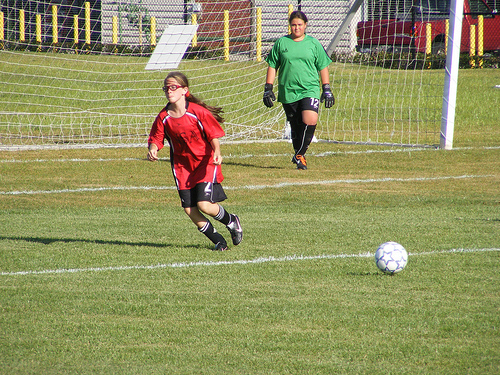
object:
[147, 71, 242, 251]
girl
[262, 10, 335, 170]
girl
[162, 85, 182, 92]
eye glass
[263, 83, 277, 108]
gloves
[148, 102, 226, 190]
shirt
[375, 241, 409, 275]
ball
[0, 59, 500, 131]
grass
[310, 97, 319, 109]
number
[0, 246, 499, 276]
line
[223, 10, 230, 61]
pole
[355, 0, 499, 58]
truck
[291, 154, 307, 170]
shoe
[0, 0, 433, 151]
goal net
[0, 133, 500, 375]
field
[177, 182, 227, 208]
shorts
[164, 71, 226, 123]
hair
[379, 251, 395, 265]
stars